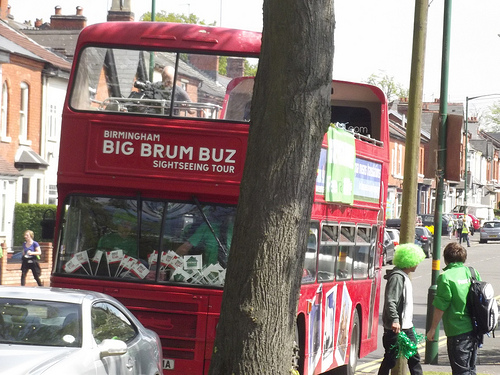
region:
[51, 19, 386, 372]
a double decker red bus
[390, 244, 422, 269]
a bright green clown wig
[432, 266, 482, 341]
a bright green shirt of a person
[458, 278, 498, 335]
a black and grey backpack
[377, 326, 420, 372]
a pair of black pants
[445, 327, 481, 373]
a pair of black pants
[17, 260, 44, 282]
a pair of black pants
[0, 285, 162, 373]
a silver car parked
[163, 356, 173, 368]
a white license plate on the bus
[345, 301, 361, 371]
the wheel of the bus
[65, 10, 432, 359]
red double decker bus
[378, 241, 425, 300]
person in a bright neon green wig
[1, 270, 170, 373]
silver 2 door car parked in front of a bus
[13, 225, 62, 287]
woman in a purple shirt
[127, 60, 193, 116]
man with a camera on top level of the bus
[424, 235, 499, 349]
person in a green jacket carrying a backpack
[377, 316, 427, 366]
person with green pom poms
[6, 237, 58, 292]
red brick wall in front of a building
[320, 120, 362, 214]
green banner hanging on side of a bus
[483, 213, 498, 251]
silver car driving on the road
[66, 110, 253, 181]
Birmingham sightseeing tour sign on bus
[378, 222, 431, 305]
Wearing fluorescent green wig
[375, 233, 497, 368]
His hair matches the other guys jacket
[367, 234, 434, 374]
Green hair and pompoms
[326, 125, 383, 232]
Bright green sign on bus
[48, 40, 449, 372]
Double decker bus parked on side of street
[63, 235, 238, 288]
A lot of banners behind windshield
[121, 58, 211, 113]
Camera man sitting on top of bus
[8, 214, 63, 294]
Pedestrian walking down the street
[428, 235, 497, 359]
Wearing a backpack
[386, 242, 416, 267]
green wig on person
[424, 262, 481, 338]
green jacket on man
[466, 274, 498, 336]
black book bag on person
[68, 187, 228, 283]
bottom front windshield of bus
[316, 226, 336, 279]
side window of bus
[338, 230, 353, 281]
side window of bus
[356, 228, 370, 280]
side window of bus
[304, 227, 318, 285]
side window of bus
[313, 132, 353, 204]
green towel hanging over bus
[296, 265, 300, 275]
stem of a tree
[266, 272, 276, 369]
bark of a tree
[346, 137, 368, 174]
top of a bus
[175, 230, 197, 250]
window of a bus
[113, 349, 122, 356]
side mirror of a car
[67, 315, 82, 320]
front of a car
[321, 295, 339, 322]
side of a bus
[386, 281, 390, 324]
arm of a man